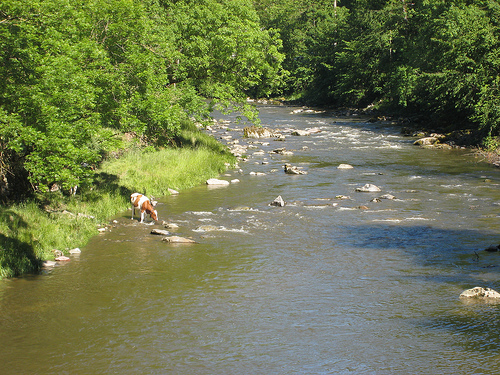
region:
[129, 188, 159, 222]
An animal drinking from the river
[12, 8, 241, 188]
The bright green tree behind the animal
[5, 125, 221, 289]
The green grass around the animal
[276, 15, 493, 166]
The darker trees in the back ground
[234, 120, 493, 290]
The rocks in the river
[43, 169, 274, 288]
The rocks closest to the grass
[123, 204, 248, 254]
The rocks closest to the animal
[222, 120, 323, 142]
A large boulder or tree in the water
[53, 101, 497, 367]
A river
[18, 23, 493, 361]
An animal drinking water from a river with trees around it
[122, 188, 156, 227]
small cow by water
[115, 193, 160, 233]
small cow by stream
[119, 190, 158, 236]
small cow by river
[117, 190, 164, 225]
cow drinking from river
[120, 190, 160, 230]
cow drinking from water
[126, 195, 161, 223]
cow drinking from stream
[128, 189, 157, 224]
white and black cow drinking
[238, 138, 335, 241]
rocks in the middle of water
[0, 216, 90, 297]
green grass by side of river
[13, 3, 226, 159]
green leaves covering trees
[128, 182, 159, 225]
a cow in a river.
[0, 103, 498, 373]
A river surrounded by forest.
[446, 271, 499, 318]
a rock in a river.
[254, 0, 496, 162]
a lush green forest.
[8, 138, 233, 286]
grass along a river.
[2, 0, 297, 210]
a tree with lots of green leaves.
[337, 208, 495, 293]
a shadow on a river.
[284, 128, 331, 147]
a long rock in a river.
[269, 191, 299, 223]
a rock in the middle of a river.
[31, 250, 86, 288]
rocks along a river.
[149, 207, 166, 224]
head of a horse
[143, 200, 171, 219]
neck of a horse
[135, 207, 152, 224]
leg of a horse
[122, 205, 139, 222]
leg of a horse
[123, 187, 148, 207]
body of a horse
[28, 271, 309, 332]
a clear body of water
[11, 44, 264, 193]
trees and bushes in background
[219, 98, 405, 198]
rocks in a river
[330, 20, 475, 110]
bunch of trees in the background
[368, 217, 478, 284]
shadows on a body of water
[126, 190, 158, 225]
white and brown cow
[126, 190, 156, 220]
a cow drinking water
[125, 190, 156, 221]
a brown and white cow drinking water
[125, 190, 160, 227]
a cow drinking water in a river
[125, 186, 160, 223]
a cow standing in a small river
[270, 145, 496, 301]
gray rocks in the river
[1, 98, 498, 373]
a small river in the country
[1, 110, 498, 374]
a river in the woods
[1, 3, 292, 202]
green trees beside the river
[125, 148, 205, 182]
green grass on the ground